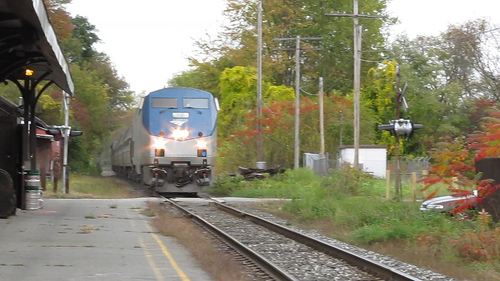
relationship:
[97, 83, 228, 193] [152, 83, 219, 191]
train has front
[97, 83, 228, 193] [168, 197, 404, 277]
train on tracks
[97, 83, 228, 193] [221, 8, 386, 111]
train besides trees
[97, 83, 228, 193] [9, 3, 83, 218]
train pulls into station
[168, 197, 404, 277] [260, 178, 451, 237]
tracks are beside grass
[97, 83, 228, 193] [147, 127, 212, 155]
train has on lights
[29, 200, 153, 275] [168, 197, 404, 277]
concrete beside tracks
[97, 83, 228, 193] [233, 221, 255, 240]
train going straight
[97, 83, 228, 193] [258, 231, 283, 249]
train faces forward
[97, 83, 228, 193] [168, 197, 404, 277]
train coming down tracks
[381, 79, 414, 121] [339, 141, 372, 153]
sign to right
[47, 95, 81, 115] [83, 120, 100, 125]
sign to left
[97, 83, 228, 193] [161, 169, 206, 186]
train has engine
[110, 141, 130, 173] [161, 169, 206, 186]
passenger cars are behind engine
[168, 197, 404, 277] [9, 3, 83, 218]
tracks are beside station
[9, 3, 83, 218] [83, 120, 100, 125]
station to left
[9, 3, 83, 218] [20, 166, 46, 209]
station has barrels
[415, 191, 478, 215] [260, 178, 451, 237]
car in grass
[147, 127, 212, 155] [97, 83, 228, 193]
lights are on train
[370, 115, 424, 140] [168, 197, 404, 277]
light before tracks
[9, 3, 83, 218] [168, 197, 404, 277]
station by tracks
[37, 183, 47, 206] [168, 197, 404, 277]
bottle beside tracks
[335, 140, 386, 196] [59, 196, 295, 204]
shed across street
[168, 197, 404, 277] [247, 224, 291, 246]
tracks have rocks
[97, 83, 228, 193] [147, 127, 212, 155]
train has lights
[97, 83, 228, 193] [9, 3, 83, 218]
train coming into station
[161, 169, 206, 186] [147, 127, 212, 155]
engine has on lights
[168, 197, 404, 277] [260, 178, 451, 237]
tracks are next to grass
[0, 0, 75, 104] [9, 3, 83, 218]
overhang of station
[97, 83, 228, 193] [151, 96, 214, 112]
train has windows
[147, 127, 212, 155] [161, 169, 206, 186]
lights are on engine